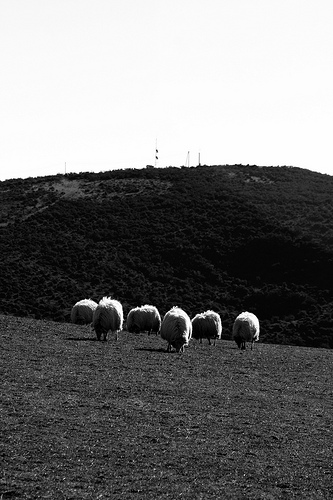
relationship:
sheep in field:
[158, 304, 194, 352] [7, 306, 323, 490]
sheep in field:
[162, 306, 191, 351] [7, 306, 323, 490]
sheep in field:
[125, 304, 160, 332] [7, 306, 323, 490]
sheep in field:
[93, 297, 122, 339] [7, 306, 323, 490]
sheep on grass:
[231, 306, 263, 345] [5, 324, 321, 488]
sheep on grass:
[192, 309, 225, 344] [5, 324, 321, 488]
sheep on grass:
[158, 304, 194, 352] [5, 324, 321, 488]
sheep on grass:
[124, 303, 161, 336] [5, 324, 321, 488]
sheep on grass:
[90, 295, 124, 340] [5, 324, 321, 488]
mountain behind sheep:
[5, 159, 322, 342] [220, 300, 268, 352]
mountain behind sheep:
[5, 159, 322, 342] [63, 294, 96, 333]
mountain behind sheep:
[5, 159, 322, 342] [153, 301, 199, 354]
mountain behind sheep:
[5, 159, 322, 342] [123, 298, 162, 344]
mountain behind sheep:
[5, 159, 322, 342] [186, 301, 225, 352]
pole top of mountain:
[185, 150, 192, 171] [5, 159, 322, 342]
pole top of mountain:
[153, 136, 159, 168] [5, 159, 322, 342]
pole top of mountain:
[196, 150, 203, 166] [5, 159, 322, 342]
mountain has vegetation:
[5, 159, 322, 342] [40, 105, 332, 309]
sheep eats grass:
[92, 296, 125, 341] [5, 311, 318, 492]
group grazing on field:
[64, 292, 266, 349] [7, 306, 323, 490]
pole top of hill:
[155, 136, 159, 168] [2, 156, 321, 323]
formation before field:
[10, 163, 316, 333] [7, 306, 323, 490]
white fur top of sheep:
[100, 295, 112, 306] [89, 294, 127, 341]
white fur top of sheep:
[100, 295, 112, 306] [234, 309, 263, 348]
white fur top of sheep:
[100, 295, 112, 306] [192, 309, 221, 347]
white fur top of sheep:
[100, 295, 112, 306] [159, 302, 192, 355]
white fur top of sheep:
[100, 295, 112, 306] [72, 295, 99, 326]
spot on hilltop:
[32, 178, 87, 200] [2, 162, 330, 192]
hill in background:
[180, 147, 287, 191] [5, 1, 321, 337]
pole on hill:
[198, 151, 201, 166] [2, 156, 321, 323]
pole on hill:
[185, 149, 191, 169] [2, 156, 321, 323]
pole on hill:
[155, 136, 159, 168] [2, 156, 321, 323]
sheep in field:
[71, 293, 94, 320] [33, 285, 294, 376]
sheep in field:
[71, 298, 99, 326] [201, 369, 308, 470]